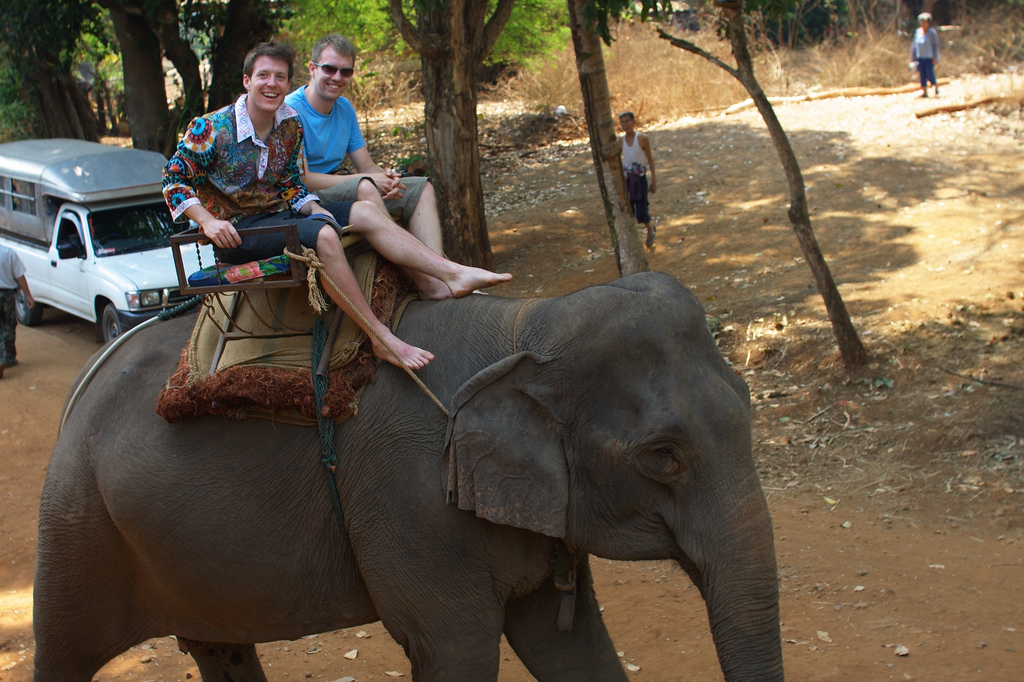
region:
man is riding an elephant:
[34, 38, 791, 681]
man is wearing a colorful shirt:
[156, 32, 517, 364]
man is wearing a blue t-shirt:
[293, 29, 518, 305]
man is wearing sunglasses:
[283, 36, 492, 296]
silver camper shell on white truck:
[0, 124, 236, 346]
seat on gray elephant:
[33, 212, 799, 681]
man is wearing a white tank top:
[608, 101, 663, 251]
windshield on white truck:
[9, 139, 218, 352]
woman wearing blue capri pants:
[911, 7, 949, 105]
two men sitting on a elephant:
[159, 27, 769, 544]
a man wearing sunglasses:
[316, 54, 359, 86]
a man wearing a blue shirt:
[300, 23, 357, 179]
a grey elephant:
[39, 257, 809, 678]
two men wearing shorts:
[155, 23, 501, 381]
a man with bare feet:
[361, 250, 510, 384]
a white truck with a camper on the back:
[5, 136, 198, 343]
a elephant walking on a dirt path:
[13, 260, 1017, 679]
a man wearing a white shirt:
[614, 117, 656, 175]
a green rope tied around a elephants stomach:
[291, 330, 387, 629]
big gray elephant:
[24, 271, 787, 680]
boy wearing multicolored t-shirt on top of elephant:
[160, 47, 509, 370]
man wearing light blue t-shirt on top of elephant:
[288, 37, 500, 300]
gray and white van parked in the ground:
[2, 129, 212, 326]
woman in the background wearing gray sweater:
[901, 11, 949, 95]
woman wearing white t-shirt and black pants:
[612, 103, 660, 243]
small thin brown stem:
[658, 3, 868, 367]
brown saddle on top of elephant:
[164, 178, 405, 407]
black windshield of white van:
[85, 197, 221, 267]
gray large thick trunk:
[689, 454, 778, 680]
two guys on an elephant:
[31, 32, 791, 680]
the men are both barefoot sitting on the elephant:
[152, 32, 513, 375]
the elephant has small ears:
[424, 339, 601, 568]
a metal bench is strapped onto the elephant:
[157, 195, 405, 383]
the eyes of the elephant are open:
[629, 427, 702, 488]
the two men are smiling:
[220, 28, 370, 133]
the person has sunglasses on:
[305, 34, 363, 115]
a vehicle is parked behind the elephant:
[9, 126, 215, 360]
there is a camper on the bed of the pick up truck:
[5, 127, 170, 290]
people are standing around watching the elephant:
[549, 12, 990, 636]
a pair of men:
[123, 34, 491, 373]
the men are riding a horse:
[19, 19, 814, 674]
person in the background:
[581, 78, 673, 238]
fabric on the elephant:
[139, 236, 367, 426]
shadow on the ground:
[367, 63, 977, 339]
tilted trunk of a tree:
[666, 18, 946, 388]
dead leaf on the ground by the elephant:
[339, 640, 362, 656]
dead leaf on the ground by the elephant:
[346, 618, 376, 656]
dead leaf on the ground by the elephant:
[361, 650, 404, 677]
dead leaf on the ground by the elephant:
[617, 656, 643, 675]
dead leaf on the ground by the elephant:
[890, 637, 907, 657]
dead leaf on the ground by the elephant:
[814, 624, 827, 641]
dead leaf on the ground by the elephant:
[835, 510, 854, 533]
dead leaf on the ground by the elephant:
[924, 552, 943, 568]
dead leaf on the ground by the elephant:
[756, 385, 776, 402]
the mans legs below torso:
[217, 202, 513, 380]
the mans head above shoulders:
[225, 33, 290, 116]